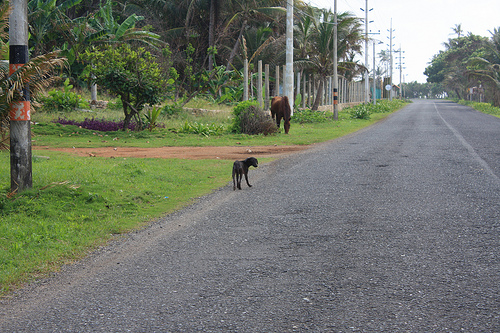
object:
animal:
[232, 156, 258, 190]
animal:
[270, 95, 292, 134]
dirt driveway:
[32, 144, 312, 159]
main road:
[1, 97, 500, 333]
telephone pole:
[364, 0, 371, 103]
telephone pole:
[386, 15, 395, 84]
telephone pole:
[396, 44, 405, 97]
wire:
[370, 0, 389, 37]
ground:
[383, 150, 403, 172]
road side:
[0, 72, 409, 333]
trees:
[76, 42, 180, 132]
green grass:
[0, 152, 226, 298]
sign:
[8, 44, 31, 121]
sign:
[333, 88, 338, 104]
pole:
[333, 0, 339, 119]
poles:
[281, 0, 339, 120]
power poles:
[0, 0, 406, 192]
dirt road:
[31, 126, 307, 168]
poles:
[245, 0, 378, 121]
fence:
[243, 59, 397, 110]